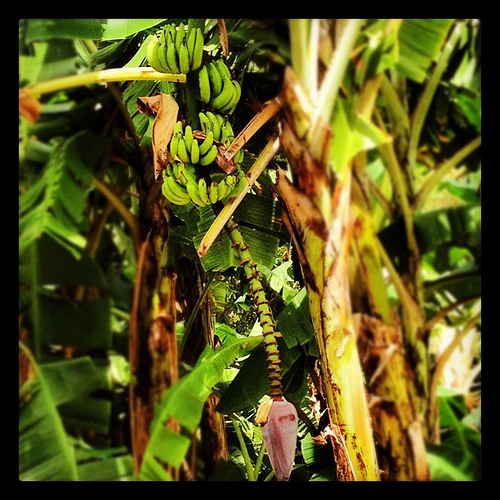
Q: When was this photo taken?
A: During the day.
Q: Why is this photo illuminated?
A: Sunlight.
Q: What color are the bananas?
A: Green.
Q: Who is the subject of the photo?
A: The jungle.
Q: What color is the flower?
A: Pink.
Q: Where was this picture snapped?
A: In the jungle.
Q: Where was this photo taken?
A: In the jungle.